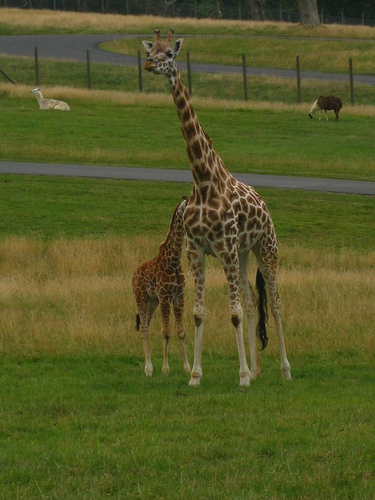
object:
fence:
[1, 47, 374, 110]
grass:
[1, 6, 374, 72]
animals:
[26, 26, 344, 389]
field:
[1, 4, 374, 178]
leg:
[159, 295, 170, 377]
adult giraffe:
[139, 23, 292, 389]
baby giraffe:
[130, 193, 193, 379]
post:
[34, 45, 39, 87]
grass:
[68, 199, 101, 248]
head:
[141, 27, 185, 77]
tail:
[253, 264, 269, 351]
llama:
[29, 87, 71, 112]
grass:
[2, 180, 46, 243]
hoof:
[238, 367, 255, 388]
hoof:
[187, 367, 203, 388]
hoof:
[280, 363, 291, 382]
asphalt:
[81, 165, 113, 177]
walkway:
[253, 172, 375, 196]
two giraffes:
[131, 27, 292, 387]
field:
[2, 171, 374, 498]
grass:
[276, 226, 372, 352]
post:
[241, 50, 248, 102]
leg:
[252, 231, 292, 382]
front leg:
[184, 238, 207, 386]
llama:
[308, 94, 344, 123]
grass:
[263, 116, 352, 164]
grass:
[3, 364, 375, 500]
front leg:
[211, 233, 251, 388]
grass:
[0, 52, 373, 181]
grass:
[0, 82, 373, 180]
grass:
[1, 408, 361, 495]